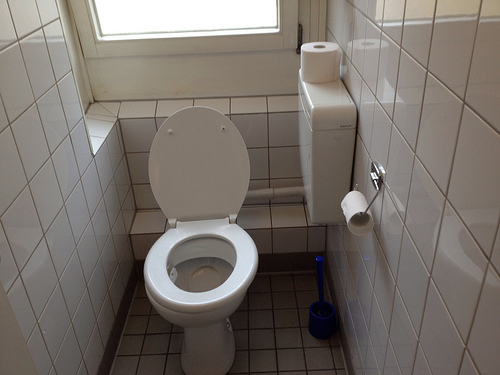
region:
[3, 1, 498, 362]
A white tiled bathroom.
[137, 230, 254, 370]
Toilet made of white porcelain.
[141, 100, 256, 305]
White toilet seat cover.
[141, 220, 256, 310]
Toilet seat not properly set.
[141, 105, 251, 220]
The toilet seat cover is up.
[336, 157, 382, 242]
Toilet paper hanging on the wall.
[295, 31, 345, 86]
A roll of toilet paper on top of the water tank.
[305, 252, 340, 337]
Blue toilet brush on the floor.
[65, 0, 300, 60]
A closed glass window behind the toilet.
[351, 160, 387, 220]
Silver toilet paper holder.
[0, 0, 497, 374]
Bathroom with white tile walls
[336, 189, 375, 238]
Roll of white toilet paper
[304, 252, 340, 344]
Blue plastic toilet bowl cleaner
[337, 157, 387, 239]
Toilet paper roll on a metal holder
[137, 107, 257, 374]
Open white toilet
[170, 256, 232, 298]
Dirty toilet bowl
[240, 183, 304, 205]
White toilet plumbing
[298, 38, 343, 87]
Unused white toilet paper roll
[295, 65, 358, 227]
White hygiene recepticle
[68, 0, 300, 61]
Bathroom window with white wood frame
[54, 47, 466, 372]
This is a toilet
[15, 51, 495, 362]
This is a toilet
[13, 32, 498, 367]
This is a toilet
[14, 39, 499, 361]
This is a toilet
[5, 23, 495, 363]
This is a toilet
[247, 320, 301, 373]
a white tiled bathroom floor.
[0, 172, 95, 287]
a white tiled bathroom wall.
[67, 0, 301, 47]
a small white bathroom window.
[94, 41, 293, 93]
a painted white bathroom wall.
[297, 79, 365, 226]
a white garbage can is on the wall.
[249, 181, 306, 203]
a short white bathroom pipe.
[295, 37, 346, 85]
a roll of toilet paper.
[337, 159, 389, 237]
a silver toilet paper holder .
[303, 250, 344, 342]
a small blue toilet brush.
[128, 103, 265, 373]
a white toilet with the top up.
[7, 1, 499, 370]
Close-up, white, functional, narrow bathroom.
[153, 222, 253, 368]
White pedestal, seat and bowl of toilet.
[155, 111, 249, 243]
Oval, open toilet lid and hinges.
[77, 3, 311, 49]
White frame, glass and light, shining through, curtainless window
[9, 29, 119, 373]
White tile wall and brown baseboard.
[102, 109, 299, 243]
Tile, forming recess and ledge, around toilet.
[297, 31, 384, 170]
Wall-mounted, white box and toilet paper on top.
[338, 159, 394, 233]
Metal holder and toilet paper roll, nearly finished.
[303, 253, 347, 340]
Blue toilet-bowl brush.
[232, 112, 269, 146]
bathroom tile is white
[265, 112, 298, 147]
bathroom tile is white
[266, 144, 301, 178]
bathroom tile is white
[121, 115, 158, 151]
bathroom tile is white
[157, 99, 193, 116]
bathroom tile is white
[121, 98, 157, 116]
bathroom tile is white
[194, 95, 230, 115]
bathroom tile is white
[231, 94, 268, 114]
bathroom tile is white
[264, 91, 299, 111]
bathroom tile is white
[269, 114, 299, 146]
bathroom tile is white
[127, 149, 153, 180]
bathroom tile is white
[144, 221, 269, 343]
the toilet is white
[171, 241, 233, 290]
water in the bowl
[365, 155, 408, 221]
the holder is silver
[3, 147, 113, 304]
the wall is tiled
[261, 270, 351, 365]
the floor is tiled